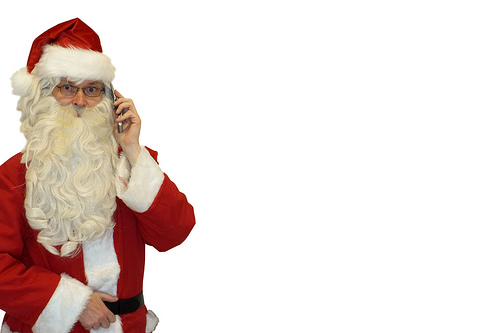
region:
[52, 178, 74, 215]
White beard of Santa Claus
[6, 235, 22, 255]
Red part of Santa claus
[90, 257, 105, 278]
White part of Santa Claus's shirt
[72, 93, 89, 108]
Nose of Santa Claus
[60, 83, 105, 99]
Glasses of Santa Claus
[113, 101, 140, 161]
Left hand of Santa Claus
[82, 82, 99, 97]
Left blue eyes of Santa Claus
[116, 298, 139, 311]
Black belt of Santa Claus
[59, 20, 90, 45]
Red part of Santa Claus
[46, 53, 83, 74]
White part of Santa Claus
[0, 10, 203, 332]
santa clause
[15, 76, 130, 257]
long curly white beard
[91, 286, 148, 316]
black belt on a costume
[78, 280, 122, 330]
hand on a black belt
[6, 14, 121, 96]
red and white santa hat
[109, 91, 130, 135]
silver small cell phone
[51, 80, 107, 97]
black wire framed glasses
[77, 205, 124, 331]
white area near the center of the suit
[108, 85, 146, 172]
right hand holding a cell phone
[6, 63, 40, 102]
white ball on the end of a hat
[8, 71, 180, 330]
the santa has glasses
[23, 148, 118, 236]
thee beard is white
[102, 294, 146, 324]
the belt is black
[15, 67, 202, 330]
the guy is on the phone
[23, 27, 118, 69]
the hat is red and white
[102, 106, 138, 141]
the phone is silver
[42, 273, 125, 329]
hand is holding the belt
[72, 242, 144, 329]
white stripe is on the jacket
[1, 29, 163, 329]
the man is talking on the phone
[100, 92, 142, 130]
the phone is a flip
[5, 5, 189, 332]
a man dressed as santa clause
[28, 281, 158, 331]
a black belt around his belly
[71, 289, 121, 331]
a hand on the belt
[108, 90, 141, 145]
a cellphone in his hand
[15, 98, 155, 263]
a long white beard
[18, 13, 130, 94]
a red and white hat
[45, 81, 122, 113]
glasses worn on face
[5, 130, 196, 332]
a red and white jacket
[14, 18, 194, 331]
a santa on the phone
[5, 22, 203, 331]
a man in a red and white suit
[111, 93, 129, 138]
santa is talking on a cell phone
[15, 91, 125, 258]
the beard is yellowed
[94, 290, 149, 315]
the belt is black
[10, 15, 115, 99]
the cap is red and white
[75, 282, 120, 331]
sant holds his belt with his right hand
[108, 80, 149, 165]
Santa holds a cell phone with his left hand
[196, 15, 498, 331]
no objects are visible in this area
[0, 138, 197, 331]
Santa's coat is red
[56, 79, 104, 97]
santa is wearing glasses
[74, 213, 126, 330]
Santa's coat has no visible buttons